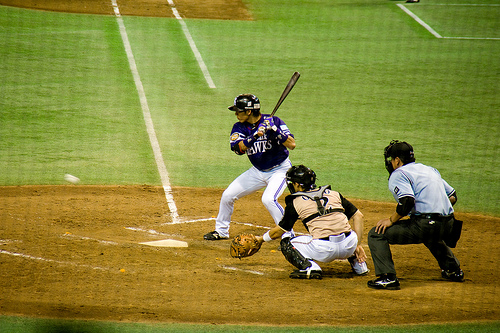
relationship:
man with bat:
[202, 91, 293, 240] [264, 70, 300, 136]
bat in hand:
[264, 70, 300, 136] [259, 118, 275, 134]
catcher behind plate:
[263, 166, 365, 273] [145, 236, 190, 250]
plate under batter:
[145, 236, 190, 250] [202, 91, 293, 240]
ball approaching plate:
[65, 172, 79, 185] [145, 236, 190, 250]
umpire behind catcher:
[367, 138, 466, 285] [263, 166, 365, 273]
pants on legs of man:
[202, 91, 293, 240] [201, 91, 297, 240]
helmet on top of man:
[225, 95, 264, 112] [202, 91, 293, 240]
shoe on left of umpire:
[364, 274, 402, 289] [367, 138, 466, 285]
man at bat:
[202, 91, 293, 240] [264, 70, 300, 136]